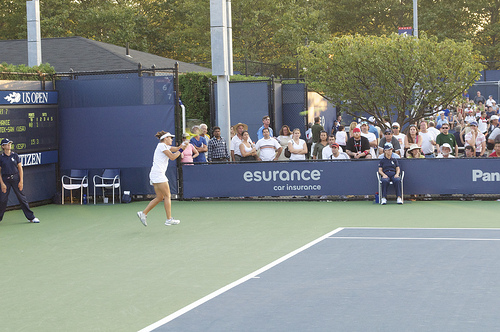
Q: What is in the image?
A: Tennis.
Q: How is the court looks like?
A: Blue.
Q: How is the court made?
A: Clay.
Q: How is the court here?
A: Green.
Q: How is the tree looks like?
A: Small.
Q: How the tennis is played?
A: Racket.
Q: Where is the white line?
A: On tennis court.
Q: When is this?
A: Daytime.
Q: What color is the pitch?
A: Blue.